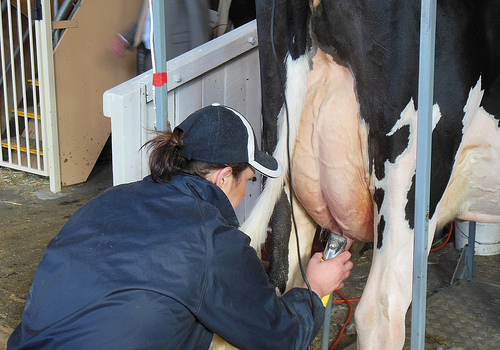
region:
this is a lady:
[72, 112, 279, 343]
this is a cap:
[198, 111, 259, 154]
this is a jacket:
[62, 200, 207, 349]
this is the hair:
[146, 126, 191, 178]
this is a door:
[202, 35, 257, 76]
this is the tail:
[284, 27, 313, 62]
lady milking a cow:
[32, 11, 479, 345]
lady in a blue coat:
[45, 83, 409, 343]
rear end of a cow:
[217, 1, 499, 343]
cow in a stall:
[103, 2, 495, 349]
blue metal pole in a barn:
[403, 7, 455, 345]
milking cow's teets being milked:
[245, 39, 446, 326]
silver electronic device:
[316, 232, 358, 273]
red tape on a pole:
[148, 66, 172, 94]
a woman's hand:
[306, 245, 356, 294]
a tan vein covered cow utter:
[283, 50, 390, 248]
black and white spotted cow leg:
[350, 92, 459, 349]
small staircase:
[3, 10, 75, 180]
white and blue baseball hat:
[171, 101, 283, 176]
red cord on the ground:
[332, 284, 366, 349]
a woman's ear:
[211, 163, 237, 189]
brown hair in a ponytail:
[134, 123, 202, 188]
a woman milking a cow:
[4, 107, 325, 348]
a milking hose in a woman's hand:
[313, 233, 347, 311]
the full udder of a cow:
[289, 158, 378, 253]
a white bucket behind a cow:
[450, 216, 498, 257]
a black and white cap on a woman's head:
[178, 102, 279, 179]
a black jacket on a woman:
[6, 170, 328, 348]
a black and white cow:
[240, 1, 498, 348]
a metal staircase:
[4, 1, 147, 176]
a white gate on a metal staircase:
[0, 1, 60, 187]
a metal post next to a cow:
[404, 0, 438, 349]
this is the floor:
[26, 205, 41, 220]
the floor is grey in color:
[16, 202, 43, 245]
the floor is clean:
[6, 192, 41, 233]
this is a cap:
[173, 99, 288, 176]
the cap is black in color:
[211, 122, 228, 142]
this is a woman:
[35, 131, 277, 333]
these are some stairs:
[18, 42, 75, 166]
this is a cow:
[261, 14, 497, 186]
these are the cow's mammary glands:
[294, 98, 373, 209]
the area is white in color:
[181, 86, 198, 101]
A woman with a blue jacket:
[42, 93, 294, 333]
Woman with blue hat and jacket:
[5, 105, 354, 349]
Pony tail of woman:
[142, 123, 181, 180]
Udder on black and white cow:
[292, 51, 374, 251]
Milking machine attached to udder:
[307, 234, 347, 305]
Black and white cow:
[237, 0, 496, 346]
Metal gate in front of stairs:
[2, 0, 55, 185]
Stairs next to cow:
[2, 0, 146, 183]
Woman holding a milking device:
[23, 102, 346, 346]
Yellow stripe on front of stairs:
[3, 75, 47, 167]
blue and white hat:
[170, 106, 279, 180]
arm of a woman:
[211, 231, 323, 344]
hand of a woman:
[302, 251, 350, 298]